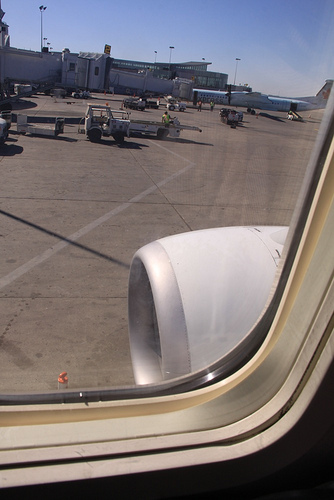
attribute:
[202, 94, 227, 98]
windows — small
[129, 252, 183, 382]
frame — silver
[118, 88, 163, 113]
vehicles — support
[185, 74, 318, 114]
airplane — white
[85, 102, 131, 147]
vehicle — small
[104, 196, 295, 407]
engine — large, white, silver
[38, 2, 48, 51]
post — tall, skinny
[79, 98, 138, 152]
runway vehicle — small, white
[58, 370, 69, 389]
cone — orange, white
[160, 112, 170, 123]
vest — reflective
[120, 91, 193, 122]
vehicles — support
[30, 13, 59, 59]
pole — large, silver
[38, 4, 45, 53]
lights — tall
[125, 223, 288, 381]
engine — silver-trimmed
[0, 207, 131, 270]
shadow — black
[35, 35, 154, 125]
building — white, small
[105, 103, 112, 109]
light — orange